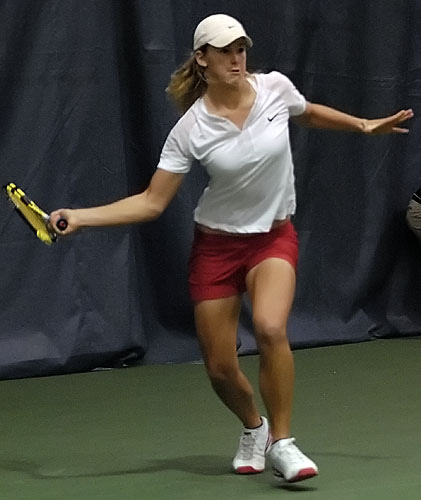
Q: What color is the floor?
A: Green.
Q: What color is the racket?
A: Yellow.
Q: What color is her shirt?
A: White.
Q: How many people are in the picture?
A: One.